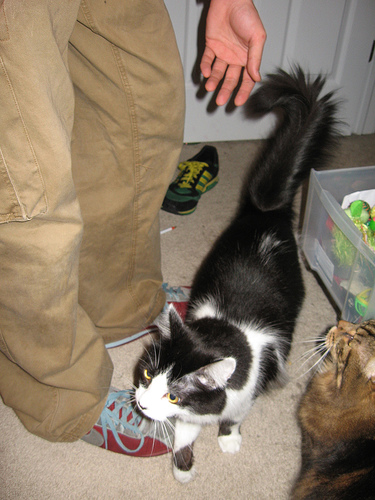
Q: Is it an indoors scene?
A: Yes, it is indoors.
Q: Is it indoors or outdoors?
A: It is indoors.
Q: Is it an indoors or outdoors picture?
A: It is indoors.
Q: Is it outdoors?
A: No, it is indoors.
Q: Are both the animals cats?
A: Yes, all the animals are cats.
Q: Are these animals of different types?
A: No, all the animals are cats.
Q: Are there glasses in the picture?
A: No, there are no glasses.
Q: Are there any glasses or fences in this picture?
A: No, there are no glasses or fences.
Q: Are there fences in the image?
A: No, there are no fences.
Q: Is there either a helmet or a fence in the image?
A: No, there are no fences or helmets.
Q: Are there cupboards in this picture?
A: No, there are no cupboards.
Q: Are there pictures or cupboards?
A: No, there are no cupboards or pictures.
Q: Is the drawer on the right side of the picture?
A: Yes, the drawer is on the right of the image.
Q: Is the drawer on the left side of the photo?
A: No, the drawer is on the right of the image.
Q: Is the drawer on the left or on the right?
A: The drawer is on the right of the image.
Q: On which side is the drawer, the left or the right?
A: The drawer is on the right of the image.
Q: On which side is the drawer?
A: The drawer is on the right of the image.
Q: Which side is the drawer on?
A: The drawer is on the right of the image.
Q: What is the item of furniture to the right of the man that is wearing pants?
A: The piece of furniture is a drawer.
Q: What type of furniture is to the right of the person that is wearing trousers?
A: The piece of furniture is a drawer.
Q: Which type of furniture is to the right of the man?
A: The piece of furniture is a drawer.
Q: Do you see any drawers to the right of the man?
A: Yes, there is a drawer to the right of the man.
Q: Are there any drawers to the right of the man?
A: Yes, there is a drawer to the right of the man.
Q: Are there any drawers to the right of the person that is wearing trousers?
A: Yes, there is a drawer to the right of the man.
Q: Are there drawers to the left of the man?
A: No, the drawer is to the right of the man.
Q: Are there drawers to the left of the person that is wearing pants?
A: No, the drawer is to the right of the man.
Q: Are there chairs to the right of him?
A: No, there is a drawer to the right of the man.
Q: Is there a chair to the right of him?
A: No, there is a drawer to the right of the man.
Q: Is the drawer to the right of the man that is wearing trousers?
A: Yes, the drawer is to the right of the man.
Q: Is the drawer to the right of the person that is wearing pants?
A: Yes, the drawer is to the right of the man.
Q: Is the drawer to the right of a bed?
A: No, the drawer is to the right of the man.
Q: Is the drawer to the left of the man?
A: No, the drawer is to the right of the man.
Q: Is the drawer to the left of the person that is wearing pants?
A: No, the drawer is to the right of the man.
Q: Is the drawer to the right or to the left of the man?
A: The drawer is to the right of the man.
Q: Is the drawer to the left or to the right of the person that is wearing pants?
A: The drawer is to the right of the man.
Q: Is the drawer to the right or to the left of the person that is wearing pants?
A: The drawer is to the right of the man.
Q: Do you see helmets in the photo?
A: No, there are no helmets.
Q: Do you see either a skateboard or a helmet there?
A: No, there are no helmets or skateboards.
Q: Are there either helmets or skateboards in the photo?
A: No, there are no helmets or skateboards.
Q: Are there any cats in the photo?
A: Yes, there is a cat.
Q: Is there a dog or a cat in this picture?
A: Yes, there is a cat.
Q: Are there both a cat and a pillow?
A: No, there is a cat but no pillows.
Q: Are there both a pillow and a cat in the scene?
A: No, there is a cat but no pillows.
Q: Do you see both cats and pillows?
A: No, there is a cat but no pillows.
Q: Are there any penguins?
A: No, there are no penguins.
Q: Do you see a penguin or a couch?
A: No, there are no penguins or couches.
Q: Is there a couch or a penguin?
A: No, there are no penguins or couches.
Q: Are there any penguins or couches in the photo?
A: No, there are no penguins or couches.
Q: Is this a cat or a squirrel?
A: This is a cat.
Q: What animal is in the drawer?
A: The cat is in the drawer.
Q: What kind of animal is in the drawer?
A: The animal is a cat.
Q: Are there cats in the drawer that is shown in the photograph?
A: Yes, there is a cat in the drawer.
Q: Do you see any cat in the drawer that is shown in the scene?
A: Yes, there is a cat in the drawer.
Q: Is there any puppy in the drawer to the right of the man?
A: No, there is a cat in the drawer.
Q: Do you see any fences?
A: No, there are no fences.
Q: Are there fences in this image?
A: No, there are no fences.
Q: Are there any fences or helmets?
A: No, there are no fences or helmets.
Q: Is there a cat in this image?
A: Yes, there is a cat.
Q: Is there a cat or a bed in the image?
A: Yes, there is a cat.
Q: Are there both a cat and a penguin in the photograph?
A: No, there is a cat but no penguins.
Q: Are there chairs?
A: No, there are no chairs.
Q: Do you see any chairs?
A: No, there are no chairs.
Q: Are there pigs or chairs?
A: No, there are no chairs or pigs.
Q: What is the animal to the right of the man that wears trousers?
A: The animal is a cat.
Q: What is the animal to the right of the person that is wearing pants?
A: The animal is a cat.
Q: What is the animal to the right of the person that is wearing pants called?
A: The animal is a cat.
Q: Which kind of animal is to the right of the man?
A: The animal is a cat.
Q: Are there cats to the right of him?
A: Yes, there is a cat to the right of the man.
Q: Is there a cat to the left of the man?
A: No, the cat is to the right of the man.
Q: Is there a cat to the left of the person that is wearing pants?
A: No, the cat is to the right of the man.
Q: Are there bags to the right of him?
A: No, there is a cat to the right of the man.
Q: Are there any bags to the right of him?
A: No, there is a cat to the right of the man.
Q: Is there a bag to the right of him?
A: No, there is a cat to the right of the man.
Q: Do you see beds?
A: No, there are no beds.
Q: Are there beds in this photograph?
A: No, there are no beds.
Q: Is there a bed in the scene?
A: No, there are no beds.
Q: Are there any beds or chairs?
A: No, there are no beds or chairs.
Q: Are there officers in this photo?
A: No, there are no officers.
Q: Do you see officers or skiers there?
A: No, there are no officers or skiers.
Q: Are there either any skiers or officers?
A: No, there are no officers or skiers.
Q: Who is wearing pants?
A: The man is wearing pants.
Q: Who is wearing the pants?
A: The man is wearing pants.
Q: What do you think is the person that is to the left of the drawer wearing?
A: The man is wearing trousers.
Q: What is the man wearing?
A: The man is wearing trousers.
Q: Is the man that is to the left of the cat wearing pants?
A: Yes, the man is wearing pants.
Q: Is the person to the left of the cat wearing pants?
A: Yes, the man is wearing pants.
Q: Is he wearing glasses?
A: No, the man is wearing pants.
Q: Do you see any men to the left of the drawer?
A: Yes, there is a man to the left of the drawer.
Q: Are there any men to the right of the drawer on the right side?
A: No, the man is to the left of the drawer.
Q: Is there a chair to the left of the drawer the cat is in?
A: No, there is a man to the left of the drawer.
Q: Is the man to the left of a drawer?
A: Yes, the man is to the left of a drawer.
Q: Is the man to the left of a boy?
A: No, the man is to the left of a drawer.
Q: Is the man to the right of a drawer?
A: No, the man is to the left of a drawer.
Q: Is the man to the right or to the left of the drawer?
A: The man is to the left of the drawer.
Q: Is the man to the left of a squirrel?
A: No, the man is to the left of the cat.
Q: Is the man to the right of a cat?
A: No, the man is to the left of a cat.